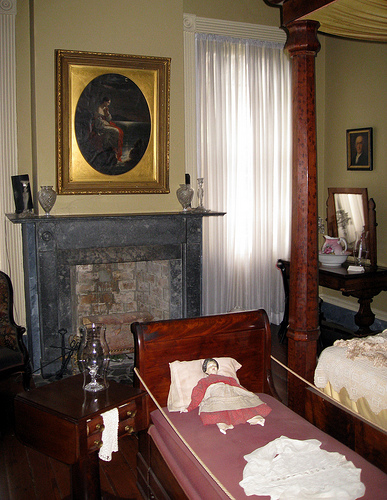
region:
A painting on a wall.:
[54, 48, 172, 197]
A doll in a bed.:
[179, 357, 271, 434]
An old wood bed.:
[128, 307, 385, 497]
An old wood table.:
[15, 371, 152, 499]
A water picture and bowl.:
[317, 233, 353, 268]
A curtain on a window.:
[192, 29, 292, 326]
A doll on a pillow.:
[165, 354, 273, 434]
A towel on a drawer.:
[95, 405, 118, 461]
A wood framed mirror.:
[325, 185, 370, 257]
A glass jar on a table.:
[76, 321, 111, 393]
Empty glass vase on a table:
[76, 319, 111, 395]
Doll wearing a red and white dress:
[177, 356, 272, 434]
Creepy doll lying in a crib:
[179, 357, 271, 434]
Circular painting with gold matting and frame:
[52, 47, 173, 197]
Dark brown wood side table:
[8, 371, 150, 499]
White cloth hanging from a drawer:
[96, 406, 120, 463]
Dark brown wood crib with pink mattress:
[128, 307, 386, 498]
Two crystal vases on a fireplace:
[35, 183, 194, 215]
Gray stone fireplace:
[11, 209, 225, 375]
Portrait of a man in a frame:
[343, 125, 375, 174]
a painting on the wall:
[44, 36, 176, 199]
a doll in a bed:
[193, 355, 265, 439]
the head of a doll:
[194, 352, 221, 377]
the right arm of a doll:
[186, 370, 211, 416]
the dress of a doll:
[187, 378, 264, 423]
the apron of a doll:
[203, 377, 235, 410]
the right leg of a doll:
[210, 422, 237, 443]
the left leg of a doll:
[246, 412, 273, 430]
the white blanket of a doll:
[247, 428, 338, 496]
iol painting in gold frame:
[56, 54, 169, 196]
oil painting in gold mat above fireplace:
[53, 47, 169, 196]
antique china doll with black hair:
[175, 350, 271, 441]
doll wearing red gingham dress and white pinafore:
[175, 350, 269, 439]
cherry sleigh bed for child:
[126, 302, 386, 495]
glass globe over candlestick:
[80, 319, 115, 396]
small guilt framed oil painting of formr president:
[344, 125, 377, 167]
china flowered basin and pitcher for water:
[315, 228, 356, 265]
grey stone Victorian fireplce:
[0, 193, 225, 365]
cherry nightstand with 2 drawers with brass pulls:
[16, 368, 154, 486]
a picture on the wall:
[56, 54, 173, 193]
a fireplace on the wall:
[82, 267, 171, 338]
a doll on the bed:
[200, 360, 269, 442]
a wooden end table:
[32, 366, 163, 454]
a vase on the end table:
[83, 325, 107, 389]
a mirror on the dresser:
[326, 186, 369, 255]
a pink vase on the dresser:
[321, 235, 349, 263]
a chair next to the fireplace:
[0, 276, 29, 386]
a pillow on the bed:
[171, 360, 239, 407]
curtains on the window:
[198, 35, 298, 310]